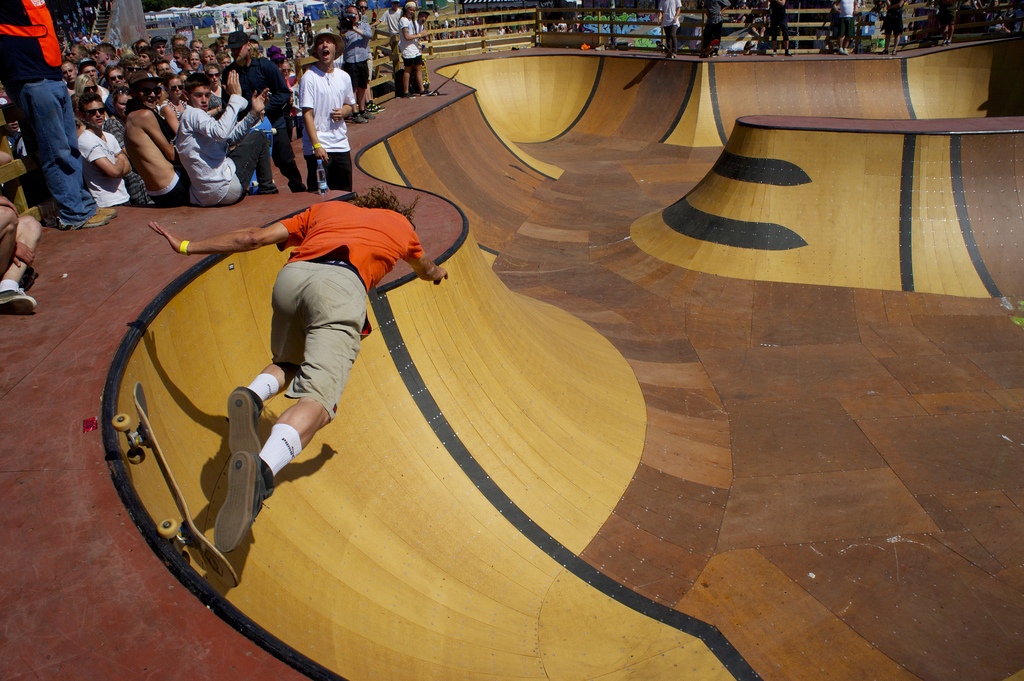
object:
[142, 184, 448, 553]
boy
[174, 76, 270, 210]
kids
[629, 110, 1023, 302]
ramp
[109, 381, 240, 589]
skateboard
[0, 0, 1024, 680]
skatepark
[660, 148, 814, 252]
design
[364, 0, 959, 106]
fence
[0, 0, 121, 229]
man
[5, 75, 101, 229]
jeans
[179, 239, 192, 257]
bracelet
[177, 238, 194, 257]
wrist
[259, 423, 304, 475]
sock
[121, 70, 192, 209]
spectator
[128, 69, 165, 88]
hat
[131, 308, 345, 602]
shadow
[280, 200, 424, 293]
shirt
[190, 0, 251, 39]
tent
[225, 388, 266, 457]
shoe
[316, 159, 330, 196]
water bottle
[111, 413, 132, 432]
wheel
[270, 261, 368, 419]
shorts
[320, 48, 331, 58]
mouth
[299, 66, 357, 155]
shirt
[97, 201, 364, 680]
rail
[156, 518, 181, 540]
wheel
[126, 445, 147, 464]
wheel